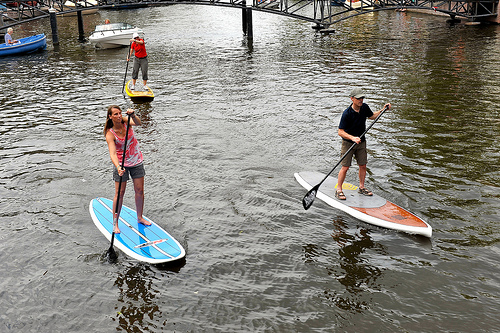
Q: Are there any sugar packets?
A: No, there are no sugar packets.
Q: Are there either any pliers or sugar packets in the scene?
A: No, there are no sugar packets or pliers.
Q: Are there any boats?
A: Yes, there is a boat.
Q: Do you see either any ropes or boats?
A: Yes, there is a boat.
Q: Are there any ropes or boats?
A: Yes, there is a boat.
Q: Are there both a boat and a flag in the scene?
A: No, there is a boat but no flags.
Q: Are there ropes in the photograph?
A: No, there are no ropes.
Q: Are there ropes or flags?
A: No, there are no ropes or flags.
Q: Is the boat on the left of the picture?
A: Yes, the boat is on the left of the image.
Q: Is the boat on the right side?
A: No, the boat is on the left of the image.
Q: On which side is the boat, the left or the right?
A: The boat is on the left of the image.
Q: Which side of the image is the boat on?
A: The boat is on the left of the image.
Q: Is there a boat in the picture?
A: Yes, there is a boat.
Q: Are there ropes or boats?
A: Yes, there is a boat.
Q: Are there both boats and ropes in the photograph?
A: No, there is a boat but no ropes.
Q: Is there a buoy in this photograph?
A: No, there are no buoys.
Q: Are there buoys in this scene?
A: No, there are no buoys.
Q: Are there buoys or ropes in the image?
A: No, there are no buoys or ropes.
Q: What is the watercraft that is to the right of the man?
A: The watercraft is a boat.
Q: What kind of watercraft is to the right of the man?
A: The watercraft is a boat.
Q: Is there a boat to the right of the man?
A: Yes, there is a boat to the right of the man.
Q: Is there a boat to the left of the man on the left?
A: No, the boat is to the right of the man.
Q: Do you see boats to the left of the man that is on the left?
A: No, the boat is to the right of the man.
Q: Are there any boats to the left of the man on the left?
A: No, the boat is to the right of the man.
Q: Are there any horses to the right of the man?
A: No, there is a boat to the right of the man.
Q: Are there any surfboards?
A: Yes, there is a surfboard.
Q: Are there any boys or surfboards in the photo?
A: Yes, there is a surfboard.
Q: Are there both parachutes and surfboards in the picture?
A: No, there is a surfboard but no parachutes.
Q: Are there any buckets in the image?
A: No, there are no buckets.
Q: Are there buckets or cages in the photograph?
A: No, there are no buckets or cages.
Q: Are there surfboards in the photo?
A: Yes, there is a surfboard.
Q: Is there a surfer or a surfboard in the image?
A: Yes, there is a surfboard.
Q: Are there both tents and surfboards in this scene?
A: No, there is a surfboard but no tents.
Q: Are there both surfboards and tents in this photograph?
A: No, there is a surfboard but no tents.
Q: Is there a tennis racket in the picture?
A: No, there are no rackets.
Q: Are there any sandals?
A: Yes, there are sandals.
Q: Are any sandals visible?
A: Yes, there are sandals.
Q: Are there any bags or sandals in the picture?
A: Yes, there are sandals.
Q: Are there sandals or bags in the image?
A: Yes, there are sandals.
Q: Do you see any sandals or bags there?
A: Yes, there are sandals.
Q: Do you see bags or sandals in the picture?
A: Yes, there are sandals.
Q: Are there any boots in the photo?
A: No, there are no boots.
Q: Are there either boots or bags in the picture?
A: No, there are no boots or bags.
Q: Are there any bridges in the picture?
A: Yes, there is a bridge.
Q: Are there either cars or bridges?
A: Yes, there is a bridge.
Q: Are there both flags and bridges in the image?
A: No, there is a bridge but no flags.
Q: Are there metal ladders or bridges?
A: Yes, there is a metal bridge.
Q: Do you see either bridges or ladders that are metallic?
A: Yes, the bridge is metallic.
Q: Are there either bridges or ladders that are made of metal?
A: Yes, the bridge is made of metal.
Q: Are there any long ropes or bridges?
A: Yes, there is a long bridge.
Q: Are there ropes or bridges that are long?
A: Yes, the bridge is long.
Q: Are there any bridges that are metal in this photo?
A: Yes, there is a metal bridge.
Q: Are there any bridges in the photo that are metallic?
A: Yes, there is a bridge that is metallic.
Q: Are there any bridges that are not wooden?
A: Yes, there is a metallic bridge.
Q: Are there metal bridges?
A: Yes, there is a bridge that is made of metal.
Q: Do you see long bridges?
A: Yes, there is a long bridge.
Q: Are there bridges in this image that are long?
A: Yes, there is a bridge that is long.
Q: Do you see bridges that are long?
A: Yes, there is a bridge that is long.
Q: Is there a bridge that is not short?
A: Yes, there is a long bridge.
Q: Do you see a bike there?
A: No, there are no bikes.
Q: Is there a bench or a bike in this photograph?
A: No, there are no bikes or benches.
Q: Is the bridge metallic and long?
A: Yes, the bridge is metallic and long.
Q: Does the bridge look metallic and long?
A: Yes, the bridge is metallic and long.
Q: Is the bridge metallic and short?
A: No, the bridge is metallic but long.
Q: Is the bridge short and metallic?
A: No, the bridge is metallic but long.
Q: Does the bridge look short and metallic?
A: No, the bridge is metallic but long.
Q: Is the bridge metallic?
A: Yes, the bridge is metallic.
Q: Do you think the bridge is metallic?
A: Yes, the bridge is metallic.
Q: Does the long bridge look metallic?
A: Yes, the bridge is metallic.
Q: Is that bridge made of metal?
A: Yes, the bridge is made of metal.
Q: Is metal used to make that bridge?
A: Yes, the bridge is made of metal.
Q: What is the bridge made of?
A: The bridge is made of metal.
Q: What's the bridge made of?
A: The bridge is made of metal.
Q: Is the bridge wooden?
A: No, the bridge is metallic.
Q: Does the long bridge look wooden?
A: No, the bridge is metallic.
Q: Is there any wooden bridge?
A: No, there is a bridge but it is metallic.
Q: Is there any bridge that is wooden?
A: No, there is a bridge but it is metallic.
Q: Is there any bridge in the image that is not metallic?
A: No, there is a bridge but it is metallic.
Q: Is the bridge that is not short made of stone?
A: No, the bridge is made of metal.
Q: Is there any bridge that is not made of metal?
A: No, there is a bridge but it is made of metal.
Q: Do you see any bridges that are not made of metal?
A: No, there is a bridge but it is made of metal.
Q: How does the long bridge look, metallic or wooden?
A: The bridge is metallic.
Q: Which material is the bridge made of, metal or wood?
A: The bridge is made of metal.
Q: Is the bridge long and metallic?
A: Yes, the bridge is long and metallic.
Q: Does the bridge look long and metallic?
A: Yes, the bridge is long and metallic.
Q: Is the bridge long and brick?
A: No, the bridge is long but metallic.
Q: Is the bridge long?
A: Yes, the bridge is long.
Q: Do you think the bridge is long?
A: Yes, the bridge is long.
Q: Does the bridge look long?
A: Yes, the bridge is long.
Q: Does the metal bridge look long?
A: Yes, the bridge is long.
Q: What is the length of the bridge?
A: The bridge is long.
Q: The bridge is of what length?
A: The bridge is long.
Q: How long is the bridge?
A: The bridge is long.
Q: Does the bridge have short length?
A: No, the bridge is long.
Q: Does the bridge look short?
A: No, the bridge is long.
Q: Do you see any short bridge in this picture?
A: No, there is a bridge but it is long.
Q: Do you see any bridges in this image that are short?
A: No, there is a bridge but it is long.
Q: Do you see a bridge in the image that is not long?
A: No, there is a bridge but it is long.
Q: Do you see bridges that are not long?
A: No, there is a bridge but it is long.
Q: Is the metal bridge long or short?
A: The bridge is long.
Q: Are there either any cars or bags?
A: No, there are no cars or bags.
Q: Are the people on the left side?
A: Yes, the people are on the left of the image.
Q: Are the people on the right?
A: No, the people are on the left of the image.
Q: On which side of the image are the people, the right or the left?
A: The people are on the left of the image.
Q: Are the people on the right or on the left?
A: The people are on the left of the image.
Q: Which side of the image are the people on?
A: The people are on the left of the image.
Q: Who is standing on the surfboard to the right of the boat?
A: The people are standing on the surfboard.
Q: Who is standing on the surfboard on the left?
A: The people are standing on the surf board.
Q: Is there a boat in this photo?
A: Yes, there is a boat.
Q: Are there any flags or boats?
A: Yes, there is a boat.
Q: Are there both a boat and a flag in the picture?
A: No, there is a boat but no flags.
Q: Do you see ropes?
A: No, there are no ropes.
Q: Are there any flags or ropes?
A: No, there are no ropes or flags.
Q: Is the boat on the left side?
A: Yes, the boat is on the left of the image.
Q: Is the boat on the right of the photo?
A: No, the boat is on the left of the image.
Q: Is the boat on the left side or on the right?
A: The boat is on the left of the image.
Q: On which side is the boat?
A: The boat is on the left of the image.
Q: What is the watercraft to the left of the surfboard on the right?
A: The watercraft is a boat.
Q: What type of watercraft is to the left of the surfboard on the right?
A: The watercraft is a boat.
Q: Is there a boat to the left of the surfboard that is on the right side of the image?
A: Yes, there is a boat to the left of the surfboard.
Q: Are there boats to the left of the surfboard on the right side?
A: Yes, there is a boat to the left of the surfboard.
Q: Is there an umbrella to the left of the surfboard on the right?
A: No, there is a boat to the left of the surfboard.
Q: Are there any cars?
A: No, there are no cars.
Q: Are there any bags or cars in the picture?
A: No, there are no cars or bags.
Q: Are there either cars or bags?
A: No, there are no cars or bags.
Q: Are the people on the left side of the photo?
A: Yes, the people are on the left of the image.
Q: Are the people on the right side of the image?
A: No, the people are on the left of the image.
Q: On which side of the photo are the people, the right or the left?
A: The people are on the left of the image.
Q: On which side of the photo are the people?
A: The people are on the left of the image.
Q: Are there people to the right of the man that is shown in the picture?
A: Yes, there are people to the right of the man.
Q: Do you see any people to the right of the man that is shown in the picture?
A: Yes, there are people to the right of the man.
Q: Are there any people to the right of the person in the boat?
A: Yes, there are people to the right of the man.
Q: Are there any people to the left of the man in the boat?
A: No, the people are to the right of the man.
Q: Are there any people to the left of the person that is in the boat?
A: No, the people are to the right of the man.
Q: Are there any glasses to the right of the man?
A: No, there are people to the right of the man.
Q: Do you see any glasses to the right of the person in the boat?
A: No, there are people to the right of the man.